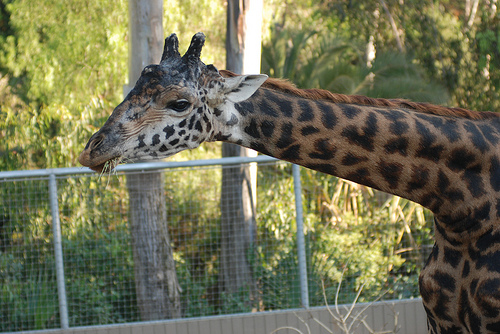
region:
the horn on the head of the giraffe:
[182, 32, 205, 63]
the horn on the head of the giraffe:
[162, 32, 179, 56]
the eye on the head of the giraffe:
[167, 98, 192, 112]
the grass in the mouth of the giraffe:
[96, 156, 133, 187]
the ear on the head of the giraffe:
[223, 73, 267, 102]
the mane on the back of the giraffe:
[219, 65, 499, 120]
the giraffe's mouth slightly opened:
[77, 153, 123, 173]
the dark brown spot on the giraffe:
[161, 123, 174, 140]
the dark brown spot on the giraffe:
[177, 117, 186, 127]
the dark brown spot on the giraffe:
[167, 138, 179, 146]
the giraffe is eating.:
[72, 32, 261, 194]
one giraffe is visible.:
[75, 24, 497, 326]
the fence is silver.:
[2, 124, 342, 329]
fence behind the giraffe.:
[2, 134, 319, 330]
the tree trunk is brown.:
[114, 1, 282, 318]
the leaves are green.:
[0, 2, 427, 293]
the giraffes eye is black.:
[166, 93, 194, 110]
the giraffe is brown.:
[73, 22, 498, 333]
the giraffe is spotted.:
[81, 27, 498, 329]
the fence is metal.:
[4, 144, 327, 331]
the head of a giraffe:
[73, 8, 256, 210]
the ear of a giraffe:
[197, 56, 261, 120]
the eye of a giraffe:
[166, 83, 211, 135]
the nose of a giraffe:
[59, 97, 139, 188]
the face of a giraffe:
[79, 8, 285, 202]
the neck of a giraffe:
[256, 70, 464, 252]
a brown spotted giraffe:
[171, 83, 436, 245]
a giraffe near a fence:
[60, 5, 370, 277]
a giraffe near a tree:
[76, 55, 271, 234]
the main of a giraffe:
[184, 43, 484, 182]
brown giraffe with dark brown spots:
[72, 30, 498, 331]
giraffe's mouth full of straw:
[92, 156, 133, 186]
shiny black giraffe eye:
[165, 93, 192, 112]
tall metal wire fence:
[0, 143, 431, 331]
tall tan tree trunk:
[122, 0, 194, 322]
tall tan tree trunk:
[210, 2, 274, 309]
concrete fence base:
[0, 299, 430, 331]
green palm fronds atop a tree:
[236, 21, 441, 138]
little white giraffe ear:
[214, 70, 268, 106]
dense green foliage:
[0, 0, 498, 328]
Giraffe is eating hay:
[80, 30, 499, 332]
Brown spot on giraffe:
[336, 110, 378, 154]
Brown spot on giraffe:
[305, 133, 340, 160]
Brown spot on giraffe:
[289, 95, 319, 124]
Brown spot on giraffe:
[375, 150, 403, 190]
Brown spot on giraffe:
[410, 111, 445, 162]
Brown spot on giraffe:
[401, 162, 431, 197]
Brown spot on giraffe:
[442, 140, 477, 173]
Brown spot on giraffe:
[410, 111, 463, 141]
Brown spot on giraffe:
[314, 95, 341, 130]